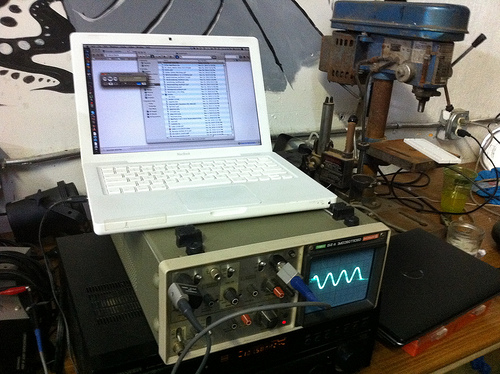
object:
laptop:
[373, 226, 499, 349]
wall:
[0, 0, 499, 160]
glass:
[439, 164, 479, 215]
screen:
[303, 247, 375, 309]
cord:
[35, 191, 92, 374]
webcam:
[167, 37, 173, 41]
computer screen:
[82, 43, 264, 153]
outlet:
[434, 105, 472, 144]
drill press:
[357, 68, 388, 178]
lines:
[305, 266, 366, 290]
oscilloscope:
[298, 247, 380, 312]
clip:
[0, 283, 34, 297]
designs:
[0, 0, 77, 95]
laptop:
[70, 30, 339, 234]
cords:
[456, 116, 500, 143]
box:
[437, 103, 467, 139]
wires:
[360, 130, 500, 216]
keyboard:
[97, 150, 297, 196]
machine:
[317, 0, 483, 195]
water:
[440, 191, 470, 214]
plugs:
[347, 170, 383, 208]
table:
[0, 160, 499, 374]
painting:
[57, 0, 333, 91]